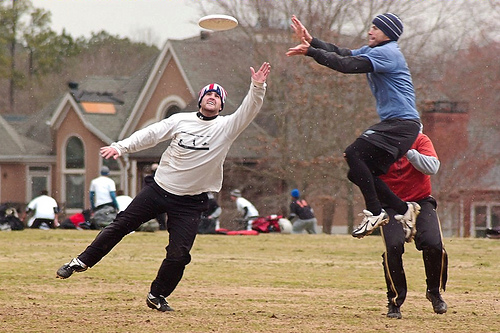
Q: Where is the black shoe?
A: On the man.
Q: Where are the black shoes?
A: On the man.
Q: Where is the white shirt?
A: On the man.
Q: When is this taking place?
A: Daylight.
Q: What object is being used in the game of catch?
A: Frisbee.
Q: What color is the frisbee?
A: White.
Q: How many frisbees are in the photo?
A: One.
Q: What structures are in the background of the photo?
A: Houses.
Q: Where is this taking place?
A: On a campus.